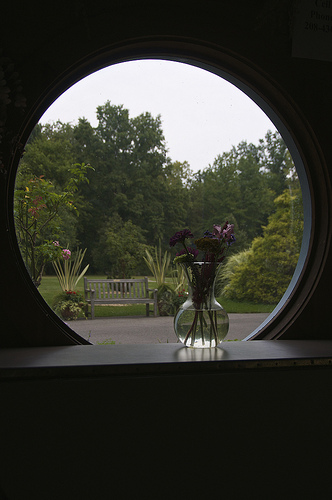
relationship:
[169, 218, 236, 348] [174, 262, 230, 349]
flowers inside vase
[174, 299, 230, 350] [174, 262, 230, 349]
bottom of vase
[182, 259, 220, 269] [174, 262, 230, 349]
opening of vase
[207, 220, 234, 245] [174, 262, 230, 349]
flower inside vase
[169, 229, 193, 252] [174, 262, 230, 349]
flower inside vase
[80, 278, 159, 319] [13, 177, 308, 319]
bench sitting in garden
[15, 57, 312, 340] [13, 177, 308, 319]
window overlooking garden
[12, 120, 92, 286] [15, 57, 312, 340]
tree outside window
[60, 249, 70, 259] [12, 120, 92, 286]
flower growing on tree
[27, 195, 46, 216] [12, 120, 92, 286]
leaves growing on tree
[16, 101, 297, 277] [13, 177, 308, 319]
trees growing in garden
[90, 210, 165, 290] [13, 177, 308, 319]
tree in middle of garden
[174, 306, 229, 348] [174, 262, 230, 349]
water inside vase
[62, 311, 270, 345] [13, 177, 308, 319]
pavement next to garden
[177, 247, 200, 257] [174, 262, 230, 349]
flower inside vase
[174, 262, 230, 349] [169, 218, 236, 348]
vase holding flowers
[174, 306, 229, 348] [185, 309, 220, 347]
water distorting stems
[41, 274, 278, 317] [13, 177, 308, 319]
grass growing in garden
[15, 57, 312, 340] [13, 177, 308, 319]
window frames garden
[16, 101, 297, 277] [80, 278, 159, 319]
trees behind bench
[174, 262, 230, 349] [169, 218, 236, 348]
vase of flowers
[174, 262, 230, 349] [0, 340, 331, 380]
vase on top of shelf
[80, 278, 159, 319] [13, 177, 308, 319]
bench situated in garden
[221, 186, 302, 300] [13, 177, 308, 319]
bush growing in garden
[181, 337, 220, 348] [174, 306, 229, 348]
light reflecting through water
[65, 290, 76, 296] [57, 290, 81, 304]
flowers inside pot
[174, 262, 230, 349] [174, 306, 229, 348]
vase filled with water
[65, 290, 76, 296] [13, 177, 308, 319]
flowers in garden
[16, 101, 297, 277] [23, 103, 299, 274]
trees growing in forest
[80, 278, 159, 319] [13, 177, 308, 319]
bench placed in garden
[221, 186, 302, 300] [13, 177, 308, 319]
bush in garden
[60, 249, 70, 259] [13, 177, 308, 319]
flower visible in garden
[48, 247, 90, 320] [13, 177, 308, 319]
plant growing in garden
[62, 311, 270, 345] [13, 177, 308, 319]
pavement in front of garden